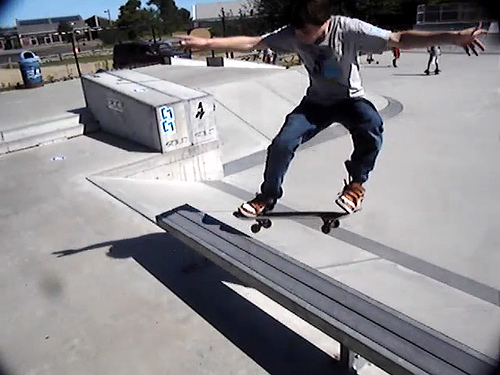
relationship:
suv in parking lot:
[111, 34, 192, 65] [5, 39, 144, 76]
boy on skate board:
[165, 4, 489, 235] [231, 207, 364, 235]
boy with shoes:
[165, 4, 489, 235] [235, 179, 369, 221]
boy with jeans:
[168, 0, 492, 219] [251, 97, 386, 204]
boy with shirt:
[168, 0, 492, 219] [264, 15, 394, 102]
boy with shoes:
[168, 0, 492, 219] [233, 184, 370, 221]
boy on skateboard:
[168, 0, 492, 219] [232, 207, 360, 233]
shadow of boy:
[50, 226, 246, 292] [168, 0, 492, 219]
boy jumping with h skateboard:
[168, 0, 492, 219] [263, 198, 339, 225]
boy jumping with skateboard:
[168, 0, 492, 219] [228, 209, 363, 236]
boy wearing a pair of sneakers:
[168, 0, 492, 219] [238, 178, 366, 218]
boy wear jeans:
[168, 0, 492, 219] [258, 97, 383, 199]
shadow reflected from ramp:
[50, 231, 357, 373] [152, 199, 499, 371]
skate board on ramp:
[232, 204, 362, 236] [71, 152, 466, 369]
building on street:
[23, 15, 157, 96] [7, 19, 127, 99]